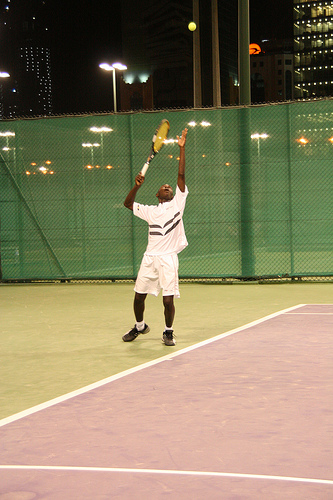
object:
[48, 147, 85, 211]
mesh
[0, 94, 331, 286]
fence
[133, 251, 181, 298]
shorts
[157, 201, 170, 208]
collar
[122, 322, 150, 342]
shoe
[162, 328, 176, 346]
shoe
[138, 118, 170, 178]
racket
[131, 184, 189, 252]
shirt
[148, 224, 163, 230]
stripes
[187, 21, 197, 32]
ball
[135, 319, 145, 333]
socks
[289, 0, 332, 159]
building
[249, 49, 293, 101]
building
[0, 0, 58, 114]
building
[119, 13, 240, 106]
building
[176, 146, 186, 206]
arm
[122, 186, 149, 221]
arm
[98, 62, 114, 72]
light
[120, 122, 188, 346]
man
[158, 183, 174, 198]
face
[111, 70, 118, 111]
pole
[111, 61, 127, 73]
street light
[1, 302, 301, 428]
lines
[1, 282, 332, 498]
ground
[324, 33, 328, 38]
building lights